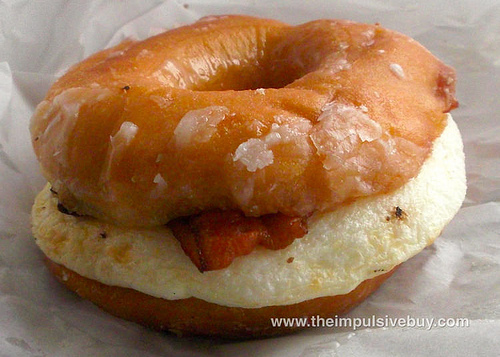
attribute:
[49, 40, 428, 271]
sandwich — white, wax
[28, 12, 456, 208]
donut — glazed, white, glaze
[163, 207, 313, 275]
bacon — brown, color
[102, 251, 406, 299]
egg — white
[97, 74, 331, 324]
sandwich — breakfast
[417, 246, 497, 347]
wax paper — white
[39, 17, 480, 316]
cooked egg — cooked 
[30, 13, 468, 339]
donut — glazed, breakfast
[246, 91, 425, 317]
sandwich — breakfast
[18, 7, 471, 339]
sandwich — round, breakfast, donut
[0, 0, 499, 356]
food wrapper — white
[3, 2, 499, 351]
paper — color, white